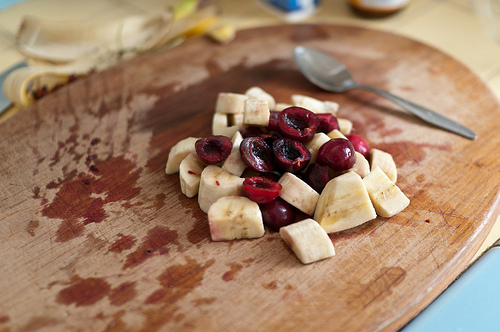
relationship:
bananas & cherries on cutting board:
[177, 92, 355, 257] [50, 249, 248, 306]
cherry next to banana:
[276, 102, 316, 140] [320, 176, 364, 232]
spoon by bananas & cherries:
[274, 47, 479, 137] [177, 92, 355, 257]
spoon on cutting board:
[274, 47, 479, 137] [50, 249, 248, 306]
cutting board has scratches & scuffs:
[50, 249, 248, 306] [375, 192, 490, 238]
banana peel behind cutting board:
[6, 25, 275, 56] [50, 249, 248, 306]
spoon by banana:
[274, 47, 479, 137] [320, 176, 364, 232]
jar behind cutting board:
[352, 4, 420, 21] [50, 249, 248, 306]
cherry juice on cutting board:
[133, 108, 161, 202] [50, 249, 248, 306]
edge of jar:
[353, 5, 368, 12] [352, 4, 420, 21]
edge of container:
[353, 5, 368, 12] [266, 2, 323, 22]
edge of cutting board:
[353, 5, 368, 12] [50, 249, 248, 306]